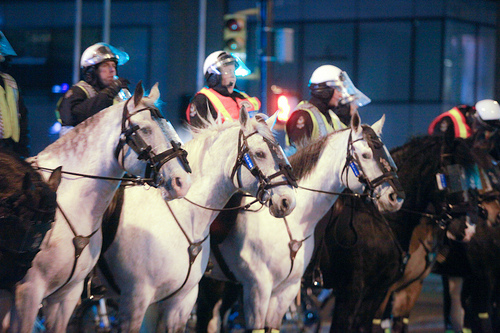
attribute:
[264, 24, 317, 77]
box — small, gray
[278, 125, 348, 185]
brown mane — dark brown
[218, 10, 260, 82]
light — yellow, street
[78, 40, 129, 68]
helmet — riot, police officer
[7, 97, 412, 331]
three horses — white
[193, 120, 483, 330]
horse — dark brown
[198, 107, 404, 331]
horse — white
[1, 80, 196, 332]
horse — white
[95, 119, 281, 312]
horse — white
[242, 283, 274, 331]
leg — horse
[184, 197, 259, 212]
rope — long, brown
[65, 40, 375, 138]
officers — three, sitting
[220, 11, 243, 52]
stoplight — green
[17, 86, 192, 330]
horses — white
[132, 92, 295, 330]
horses — white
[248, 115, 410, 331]
horses — white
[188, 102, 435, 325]
horse — dark brown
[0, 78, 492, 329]
horses — white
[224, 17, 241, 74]
light — green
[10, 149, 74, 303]
horse — brown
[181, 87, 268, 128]
vest — yellow, orange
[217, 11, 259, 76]
light — yellow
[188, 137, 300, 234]
horse — white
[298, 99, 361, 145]
vest — yellow, silver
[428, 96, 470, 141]
safety jacket — red, yellow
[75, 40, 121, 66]
helmet — white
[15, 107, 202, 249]
horse — white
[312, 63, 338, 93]
helmet — white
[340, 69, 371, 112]
helmet shield — clear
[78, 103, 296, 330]
horse — white